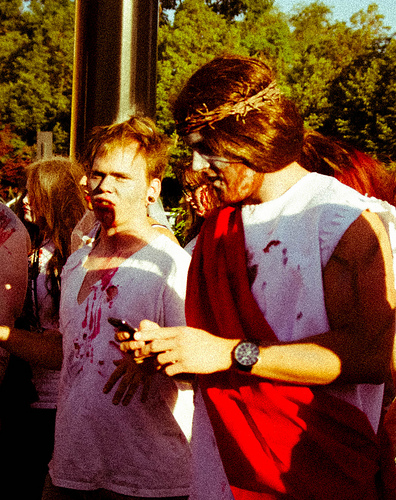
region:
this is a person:
[169, 36, 394, 399]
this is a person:
[57, 118, 182, 497]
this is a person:
[4, 122, 91, 437]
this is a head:
[170, 34, 315, 210]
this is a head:
[12, 148, 103, 243]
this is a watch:
[226, 327, 280, 392]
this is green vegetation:
[316, 9, 392, 125]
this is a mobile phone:
[94, 300, 163, 379]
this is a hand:
[137, 327, 350, 393]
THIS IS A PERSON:
[20, 151, 76, 268]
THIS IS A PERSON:
[73, 144, 162, 328]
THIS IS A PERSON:
[189, 78, 393, 389]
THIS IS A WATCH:
[218, 343, 270, 372]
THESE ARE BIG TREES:
[15, 21, 64, 69]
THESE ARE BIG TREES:
[163, 6, 214, 49]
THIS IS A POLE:
[72, 13, 153, 99]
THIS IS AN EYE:
[111, 168, 134, 184]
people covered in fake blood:
[5, 28, 364, 486]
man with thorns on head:
[167, 48, 318, 225]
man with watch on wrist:
[156, 43, 302, 493]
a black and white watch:
[228, 328, 266, 377]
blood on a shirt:
[236, 227, 307, 314]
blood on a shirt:
[58, 246, 129, 420]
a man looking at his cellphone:
[105, 36, 288, 399]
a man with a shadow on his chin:
[85, 105, 173, 228]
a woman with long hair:
[7, 151, 89, 302]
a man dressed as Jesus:
[158, 51, 395, 332]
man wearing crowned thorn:
[168, 62, 294, 166]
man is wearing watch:
[220, 326, 268, 392]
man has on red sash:
[188, 268, 318, 482]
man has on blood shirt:
[229, 185, 307, 313]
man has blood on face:
[200, 141, 272, 219]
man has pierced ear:
[80, 145, 175, 220]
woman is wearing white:
[13, 161, 77, 300]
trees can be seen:
[258, 8, 383, 112]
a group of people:
[0, 58, 381, 497]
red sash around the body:
[180, 207, 384, 498]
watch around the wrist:
[229, 335, 265, 386]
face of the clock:
[233, 342, 259, 365]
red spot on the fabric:
[258, 237, 286, 254]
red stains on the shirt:
[59, 280, 143, 397]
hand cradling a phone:
[101, 304, 173, 382]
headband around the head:
[170, 74, 291, 142]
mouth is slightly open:
[93, 193, 115, 209]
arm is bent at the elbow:
[137, 216, 395, 407]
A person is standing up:
[42, 106, 191, 498]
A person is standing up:
[106, 51, 395, 498]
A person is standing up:
[21, 158, 89, 464]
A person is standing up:
[172, 155, 218, 255]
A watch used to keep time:
[233, 338, 260, 376]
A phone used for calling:
[108, 316, 137, 339]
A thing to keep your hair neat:
[174, 76, 282, 135]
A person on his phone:
[108, 54, 395, 497]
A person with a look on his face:
[49, 113, 190, 498]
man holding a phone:
[92, 50, 383, 409]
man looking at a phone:
[103, 25, 394, 432]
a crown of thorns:
[167, 60, 289, 150]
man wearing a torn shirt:
[43, 211, 201, 495]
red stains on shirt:
[56, 262, 134, 391]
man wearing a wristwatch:
[219, 340, 271, 376]